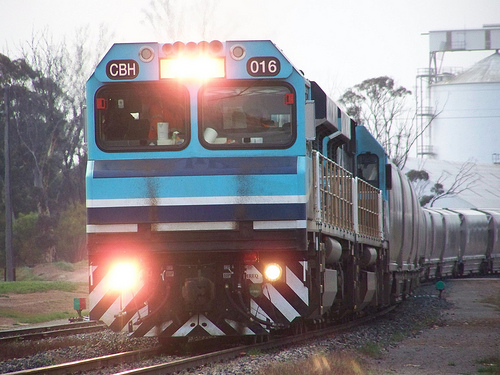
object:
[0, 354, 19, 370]
rockes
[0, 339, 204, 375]
tracks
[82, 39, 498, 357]
train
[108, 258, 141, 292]
light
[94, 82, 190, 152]
window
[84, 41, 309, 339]
front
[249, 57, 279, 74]
number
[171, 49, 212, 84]
light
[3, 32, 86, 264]
trees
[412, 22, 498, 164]
structure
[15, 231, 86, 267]
fence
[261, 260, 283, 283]
light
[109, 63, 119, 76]
letters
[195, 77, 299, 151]
window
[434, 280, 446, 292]
circle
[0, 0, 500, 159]
background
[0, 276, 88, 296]
grass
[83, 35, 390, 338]
engine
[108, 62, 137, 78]
cbh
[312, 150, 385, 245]
railing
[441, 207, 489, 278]
cars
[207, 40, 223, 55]
horns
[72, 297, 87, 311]
reflector